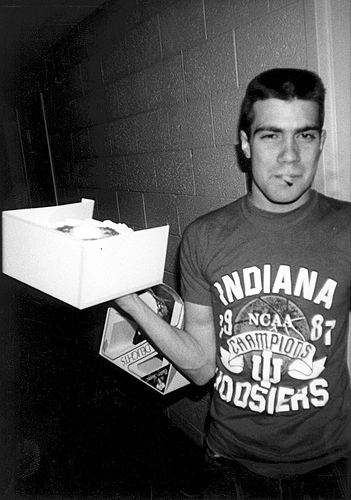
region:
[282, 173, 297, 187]
A cigarette.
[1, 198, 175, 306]
A box holding the cake.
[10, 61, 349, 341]
Man holding the cake box.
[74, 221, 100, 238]
Cream on top.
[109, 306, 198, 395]
A box on the wall.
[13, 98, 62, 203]
Office door.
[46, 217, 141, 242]
A buttercream cake.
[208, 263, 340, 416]
Indiana State championship taste.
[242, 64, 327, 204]
A young man smoking.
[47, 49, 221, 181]
A cinderblock wall.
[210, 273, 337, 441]
letters on the shirt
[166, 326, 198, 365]
the mans arm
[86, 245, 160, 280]
a white box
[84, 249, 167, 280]
a box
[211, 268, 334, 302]
letters on the shirt is white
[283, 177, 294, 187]
the man is smoking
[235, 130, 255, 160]
the mans ear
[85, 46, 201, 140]
a brick wall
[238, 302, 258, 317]
a basketball on shirt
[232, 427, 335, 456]
the mans shirt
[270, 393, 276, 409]
white fabric on shirt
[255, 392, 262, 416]
white fabric on shirt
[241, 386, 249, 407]
white fabric on shirt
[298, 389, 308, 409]
white fabric on shirt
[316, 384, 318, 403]
white fabric on shirt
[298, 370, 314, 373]
white fabric on shirt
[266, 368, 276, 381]
white fabric on shirt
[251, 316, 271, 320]
white fabric on shirt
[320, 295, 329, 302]
white fabric on shirt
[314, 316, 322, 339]
white fabric on shirt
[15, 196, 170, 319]
man holding a box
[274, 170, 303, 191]
man with a cigarette in his mouth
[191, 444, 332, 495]
man wearing black pants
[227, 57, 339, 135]
man with black cropped hair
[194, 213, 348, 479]
man wearing a tee shirt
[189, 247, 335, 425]
man wearing a Indiana Hoosier shirt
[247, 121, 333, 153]
man with bushy eyebrows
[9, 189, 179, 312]
man holding a white box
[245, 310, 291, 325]
NCAA letters on the tee shirt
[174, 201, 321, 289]
man wearing a gray shirt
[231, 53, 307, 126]
man has dark hair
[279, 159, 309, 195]
man is smoking cigarette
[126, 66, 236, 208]
brick wall behind man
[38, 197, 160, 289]
man is holding box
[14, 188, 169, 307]
cake in white box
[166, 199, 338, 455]
man has red shirt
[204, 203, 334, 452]
red shirt with college name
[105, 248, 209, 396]
box has top flap opened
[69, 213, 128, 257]
light icing on cake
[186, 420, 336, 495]
man has dark pants